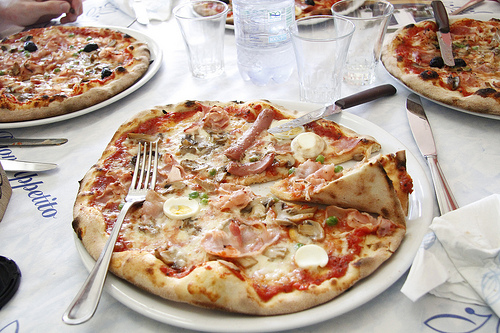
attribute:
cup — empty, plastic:
[170, 2, 231, 82]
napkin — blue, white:
[403, 193, 498, 318]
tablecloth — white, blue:
[9, 141, 75, 308]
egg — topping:
[164, 196, 197, 220]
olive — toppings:
[85, 40, 95, 50]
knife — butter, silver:
[407, 90, 458, 218]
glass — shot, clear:
[294, 14, 354, 84]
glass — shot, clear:
[286, 14, 352, 98]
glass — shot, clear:
[325, 0, 392, 83]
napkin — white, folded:
[403, 191, 496, 302]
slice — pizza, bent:
[271, 150, 412, 220]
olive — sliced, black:
[83, 40, 98, 53]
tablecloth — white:
[12, 220, 65, 308]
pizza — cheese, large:
[74, 101, 414, 313]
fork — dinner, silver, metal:
[64, 139, 158, 324]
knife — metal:
[405, 88, 456, 215]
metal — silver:
[405, 89, 459, 216]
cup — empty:
[171, 0, 227, 80]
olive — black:
[99, 66, 111, 81]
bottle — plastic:
[231, 0, 300, 90]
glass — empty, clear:
[168, 0, 229, 81]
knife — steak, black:
[266, 81, 398, 138]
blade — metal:
[270, 102, 342, 134]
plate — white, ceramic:
[73, 97, 436, 331]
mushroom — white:
[162, 193, 200, 220]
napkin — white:
[399, 185, 499, 319]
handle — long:
[62, 198, 133, 326]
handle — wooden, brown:
[335, 82, 395, 113]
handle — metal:
[425, 153, 457, 217]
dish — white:
[70, 98, 435, 331]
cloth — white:
[0, 4, 497, 331]